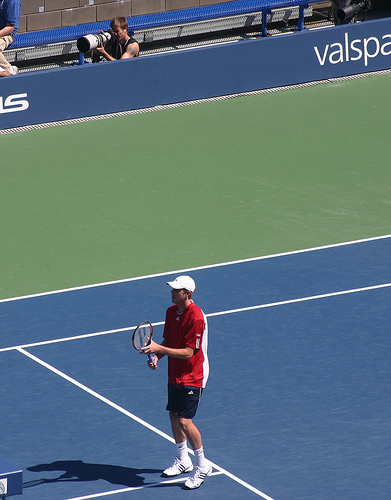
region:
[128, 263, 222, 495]
tennis player in tennis court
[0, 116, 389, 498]
tennis court is blue and green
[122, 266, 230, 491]
man wears red tee shirt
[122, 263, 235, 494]
man wears a white cup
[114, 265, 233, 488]
tennis player holds a racket with both hands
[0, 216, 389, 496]
tennis court has white lines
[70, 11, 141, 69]
man holding a camera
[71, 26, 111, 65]
camera lens is large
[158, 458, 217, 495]
white shoes with blue stripes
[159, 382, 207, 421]
the short is black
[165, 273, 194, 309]
Man wearing white cap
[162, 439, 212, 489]
Man wearing white socks and shoes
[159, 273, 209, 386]
Man wearing red and white shirt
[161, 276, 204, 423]
Man wearing red shirt and black shorts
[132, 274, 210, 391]
Man in red shirt holding tennis racket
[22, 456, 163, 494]
Shadow of man on blue tennis court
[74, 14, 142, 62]
Man pointing large camera at court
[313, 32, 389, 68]
White letters on blue wall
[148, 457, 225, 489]
White line on court between man's feet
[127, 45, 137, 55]
Large tattoo on man's arm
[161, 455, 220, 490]
Man wearing shoes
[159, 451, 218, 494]
Man is wearing shoes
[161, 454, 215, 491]
Man wearing white and black shoes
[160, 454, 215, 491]
Man is wearing white and black shoes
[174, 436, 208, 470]
Man wearing socks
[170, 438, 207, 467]
Man is wearing socks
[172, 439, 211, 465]
Man wearing white socks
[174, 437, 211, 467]
Man is wearing white socks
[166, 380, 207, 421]
Man wearing black and white socks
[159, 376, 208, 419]
Man is wearing black and white socks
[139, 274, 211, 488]
Man on the tennis court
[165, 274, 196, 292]
White hat on the man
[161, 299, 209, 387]
Shirt on the man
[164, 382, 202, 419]
Shorts on the man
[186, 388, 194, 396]
Brand logo on the man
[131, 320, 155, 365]
Racket in the man's hands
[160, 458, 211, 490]
Shoes on the man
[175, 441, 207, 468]
Socks on the man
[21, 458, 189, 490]
Shadow of the man on the tennis court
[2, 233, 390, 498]
White lines on the tennis court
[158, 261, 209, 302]
head of a person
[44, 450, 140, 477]
shadow of a person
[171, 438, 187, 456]
leg of a person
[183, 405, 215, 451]
leg of a person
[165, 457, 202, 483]
feet of a person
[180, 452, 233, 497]
feet of a person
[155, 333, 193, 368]
an arm of a person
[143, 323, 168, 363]
an arm of a person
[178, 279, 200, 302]
ear of a person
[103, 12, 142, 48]
head of a person